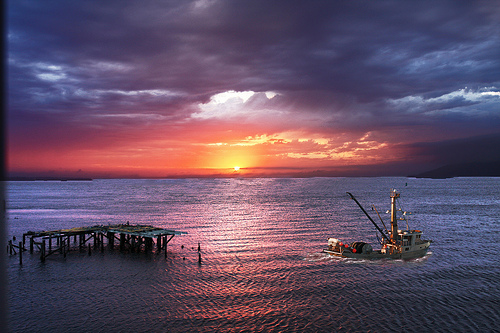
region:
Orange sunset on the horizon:
[10, 128, 384, 176]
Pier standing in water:
[12, 218, 183, 252]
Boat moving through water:
[328, 188, 428, 262]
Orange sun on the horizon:
[229, 160, 241, 175]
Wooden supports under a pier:
[45, 238, 153, 251]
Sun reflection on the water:
[168, 201, 304, 282]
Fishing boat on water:
[318, 185, 433, 262]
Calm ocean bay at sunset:
[8, 176, 496, 331]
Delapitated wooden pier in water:
[4, 220, 209, 271]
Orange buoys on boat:
[335, 239, 357, 256]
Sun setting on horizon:
[231, 163, 244, 173]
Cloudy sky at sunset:
[5, 11, 497, 170]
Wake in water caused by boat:
[301, 251, 434, 265]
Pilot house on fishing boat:
[401, 231, 427, 246]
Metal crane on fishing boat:
[344, 190, 389, 243]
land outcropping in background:
[418, 155, 499, 180]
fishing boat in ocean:
[325, 174, 440, 274]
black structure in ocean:
[31, 218, 182, 265]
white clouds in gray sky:
[390, 43, 450, 104]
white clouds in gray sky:
[28, 116, 95, 156]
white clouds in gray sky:
[156, 15, 196, 37]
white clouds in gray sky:
[293, 115, 339, 145]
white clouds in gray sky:
[323, 12, 379, 83]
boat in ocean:
[330, 176, 433, 270]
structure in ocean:
[23, 212, 176, 262]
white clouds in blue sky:
[93, 30, 127, 55]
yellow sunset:
[208, 157, 250, 174]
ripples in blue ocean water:
[210, 198, 268, 230]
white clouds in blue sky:
[239, 43, 294, 78]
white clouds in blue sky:
[434, 40, 486, 82]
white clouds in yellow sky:
[293, 134, 345, 163]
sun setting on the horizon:
[7, 90, 497, 178]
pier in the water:
[7, 220, 202, 270]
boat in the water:
[321, 185, 433, 262]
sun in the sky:
[231, 163, 243, 171]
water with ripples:
[9, 179, 498, 331]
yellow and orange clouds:
[209, 128, 404, 160]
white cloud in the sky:
[188, 86, 287, 118]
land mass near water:
[415, 158, 498, 178]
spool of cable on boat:
[350, 239, 373, 254]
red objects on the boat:
[337, 241, 357, 252]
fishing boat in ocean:
[318, 168, 440, 282]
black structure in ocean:
[26, 215, 171, 265]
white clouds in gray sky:
[52, 34, 113, 79]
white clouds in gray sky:
[282, 40, 347, 82]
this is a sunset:
[67, 45, 374, 222]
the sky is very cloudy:
[98, 43, 309, 140]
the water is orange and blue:
[131, 186, 305, 237]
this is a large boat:
[324, 174, 452, 254]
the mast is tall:
[320, 180, 412, 250]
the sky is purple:
[86, 90, 269, 220]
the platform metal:
[34, 211, 184, 262]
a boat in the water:
[349, 170, 446, 294]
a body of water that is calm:
[253, 198, 436, 310]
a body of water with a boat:
[201, 181, 381, 312]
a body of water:
[216, 193, 307, 287]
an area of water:
[206, 187, 316, 293]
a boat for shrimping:
[323, 155, 448, 309]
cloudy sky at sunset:
[2, 2, 499, 178]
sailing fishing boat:
[323, 186, 431, 263]